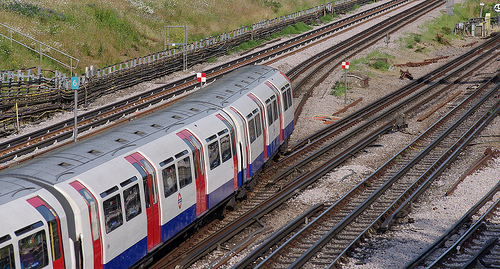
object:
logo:
[175, 192, 185, 209]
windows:
[99, 195, 128, 233]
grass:
[1, 0, 500, 98]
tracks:
[0, 1, 499, 264]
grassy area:
[0, 3, 262, 70]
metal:
[291, 43, 301, 48]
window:
[177, 150, 194, 188]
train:
[2, 65, 294, 267]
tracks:
[396, 43, 499, 128]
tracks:
[263, 77, 498, 241]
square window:
[249, 117, 258, 142]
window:
[78, 185, 102, 242]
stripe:
[223, 197, 252, 220]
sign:
[339, 60, 351, 70]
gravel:
[337, 134, 495, 267]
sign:
[63, 73, 87, 95]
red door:
[180, 121, 215, 223]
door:
[132, 158, 162, 242]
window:
[20, 235, 45, 265]